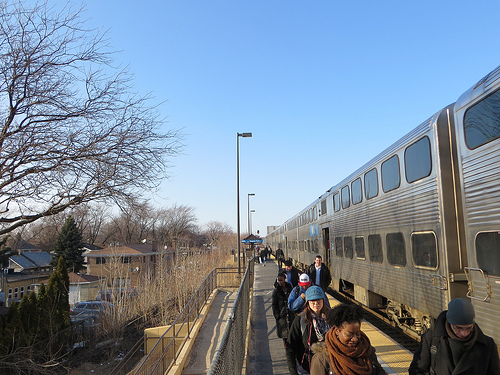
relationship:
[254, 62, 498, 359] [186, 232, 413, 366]
train at station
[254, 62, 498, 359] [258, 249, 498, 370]
train has passengers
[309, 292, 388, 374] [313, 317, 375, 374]
woman wears scarf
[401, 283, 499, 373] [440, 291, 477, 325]
person wears hat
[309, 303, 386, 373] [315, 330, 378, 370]
woman wears scarf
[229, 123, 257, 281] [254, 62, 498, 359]
post right train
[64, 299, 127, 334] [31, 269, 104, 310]
cars next building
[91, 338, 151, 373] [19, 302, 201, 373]
litter on ground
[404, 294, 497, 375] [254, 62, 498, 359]
passengers next train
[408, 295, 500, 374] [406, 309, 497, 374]
person wearing coat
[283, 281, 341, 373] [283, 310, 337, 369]
person wearing coat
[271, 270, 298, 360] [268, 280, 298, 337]
person wearing coat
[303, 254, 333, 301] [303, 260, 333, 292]
person wearing coat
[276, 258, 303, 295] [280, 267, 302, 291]
person wearing coat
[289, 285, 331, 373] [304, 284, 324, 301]
woman wearing cap